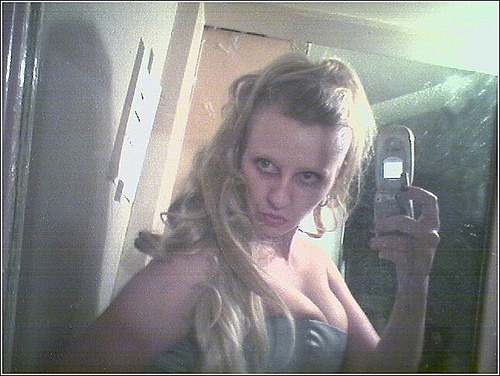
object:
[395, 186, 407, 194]
polish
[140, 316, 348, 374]
top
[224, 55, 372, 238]
head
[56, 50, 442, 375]
woman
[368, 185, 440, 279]
hand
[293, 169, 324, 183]
eye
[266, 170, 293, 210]
nose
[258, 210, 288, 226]
mouth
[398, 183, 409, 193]
finger nail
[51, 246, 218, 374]
arm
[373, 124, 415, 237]
cell phone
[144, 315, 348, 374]
dress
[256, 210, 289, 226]
lipstick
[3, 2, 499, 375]
doorway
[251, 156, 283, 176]
eye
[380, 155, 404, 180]
screen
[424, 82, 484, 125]
scratches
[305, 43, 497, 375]
mirror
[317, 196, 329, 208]
earring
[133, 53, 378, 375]
hair